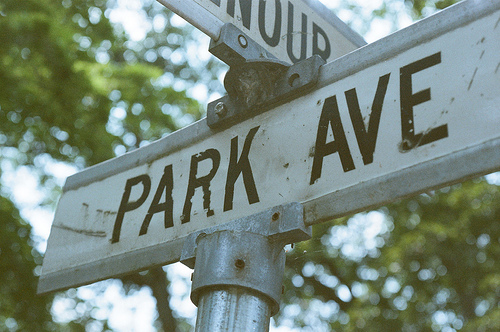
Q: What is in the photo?
A: Street signs.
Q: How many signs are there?
A: Two.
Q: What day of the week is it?
A: Tuesday.